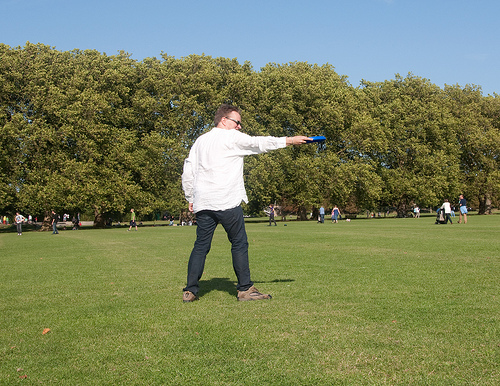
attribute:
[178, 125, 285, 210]
white long sleeve — is long, is white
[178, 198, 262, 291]
blue jeans — dark blue, crinkled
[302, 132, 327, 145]
frisbee — blue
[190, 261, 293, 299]
shadow — man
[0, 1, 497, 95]
sky is blue — clear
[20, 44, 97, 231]
tall tree — Tall , green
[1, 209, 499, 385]
green grass — green , manicured, well manicured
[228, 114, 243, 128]
black glasses — black 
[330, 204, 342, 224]
dress — blue 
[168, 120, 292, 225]
shirt — white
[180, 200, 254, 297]
pants — black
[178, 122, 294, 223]
shirt — white 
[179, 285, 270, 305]
tennis-shoes — brown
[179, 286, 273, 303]
shoe — brown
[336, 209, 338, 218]
dress — blue